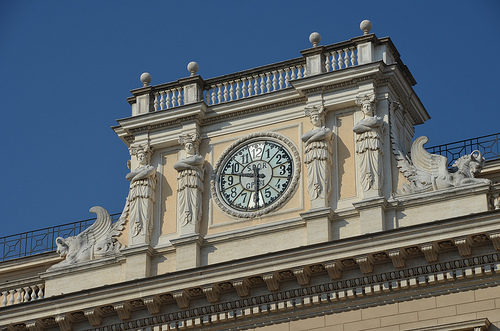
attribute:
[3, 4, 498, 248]
sky — blue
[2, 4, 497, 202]
sky — light blue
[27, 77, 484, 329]
building — tan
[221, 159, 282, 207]
arms — black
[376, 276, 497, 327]
bricks — beige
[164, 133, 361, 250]
clock — black and white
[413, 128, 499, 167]
railing — decorative, metal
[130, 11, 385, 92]
balls — cement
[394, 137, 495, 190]
statue — winged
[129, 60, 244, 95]
globes — concrete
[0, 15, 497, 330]
wall — tan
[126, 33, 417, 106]
pillars — brown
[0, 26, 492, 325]
buliding — classical architechure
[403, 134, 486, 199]
statue — winged creature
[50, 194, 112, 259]
statue — winged creature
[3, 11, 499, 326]
building — brick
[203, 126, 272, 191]
hands — black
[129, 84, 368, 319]
building — stone made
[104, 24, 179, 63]
clouds — white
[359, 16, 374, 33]
globe — concrete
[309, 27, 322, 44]
globe — concrete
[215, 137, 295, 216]
clock — blue, white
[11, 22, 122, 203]
sky — blue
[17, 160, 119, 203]
clouds — white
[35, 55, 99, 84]
clouds — white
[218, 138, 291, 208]
face — white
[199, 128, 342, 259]
clock — ornate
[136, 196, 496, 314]
ledge — of roof